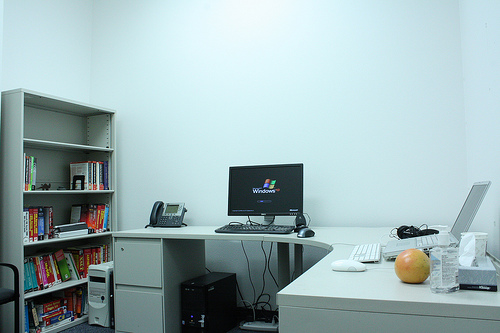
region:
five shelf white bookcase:
[0, 88, 145, 329]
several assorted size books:
[0, 147, 140, 332]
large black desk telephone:
[121, 186, 209, 259]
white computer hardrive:
[72, 251, 142, 329]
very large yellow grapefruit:
[390, 243, 432, 301]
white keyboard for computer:
[325, 216, 392, 304]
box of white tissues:
[447, 228, 495, 303]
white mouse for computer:
[312, 218, 412, 295]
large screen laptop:
[350, 151, 492, 292]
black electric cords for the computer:
[377, 210, 446, 253]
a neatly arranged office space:
[1, 0, 492, 326]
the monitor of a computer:
[225, 160, 300, 215]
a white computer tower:
[80, 260, 105, 325]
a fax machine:
[145, 195, 180, 225]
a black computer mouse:
[295, 225, 310, 235]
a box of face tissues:
[459, 252, 495, 285]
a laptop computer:
[380, 175, 490, 250]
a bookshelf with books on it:
[0, 80, 115, 325]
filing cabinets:
[110, 235, 155, 325]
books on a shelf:
[25, 207, 55, 238]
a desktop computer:
[194, 147, 333, 278]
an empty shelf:
[2, 68, 166, 167]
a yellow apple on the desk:
[380, 232, 465, 298]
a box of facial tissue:
[447, 213, 498, 289]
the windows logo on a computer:
[194, 143, 346, 253]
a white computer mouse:
[312, 251, 385, 299]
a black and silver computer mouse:
[284, 216, 331, 261]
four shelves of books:
[12, 139, 139, 331]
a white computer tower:
[64, 231, 139, 332]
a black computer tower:
[162, 247, 261, 332]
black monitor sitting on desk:
[223, 144, 350, 236]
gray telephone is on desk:
[151, 177, 198, 244]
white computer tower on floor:
[86, 249, 123, 326]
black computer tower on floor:
[173, 269, 255, 331]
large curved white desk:
[116, 217, 498, 312]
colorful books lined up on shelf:
[28, 202, 115, 229]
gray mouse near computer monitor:
[301, 214, 328, 244]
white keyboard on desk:
[346, 234, 391, 279]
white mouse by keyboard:
[321, 262, 373, 279]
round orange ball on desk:
[376, 239, 436, 279]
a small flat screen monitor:
[221, 157, 306, 219]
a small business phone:
[145, 196, 188, 228]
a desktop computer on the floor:
[84, 255, 113, 329]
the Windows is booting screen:
[242, 175, 293, 207]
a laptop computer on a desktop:
[380, 171, 492, 261]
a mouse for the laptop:
[325, 255, 366, 272]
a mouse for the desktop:
[292, 223, 314, 238]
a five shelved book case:
[0, 87, 115, 329]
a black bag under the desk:
[176, 268, 237, 328]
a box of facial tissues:
[453, 229, 493, 287]